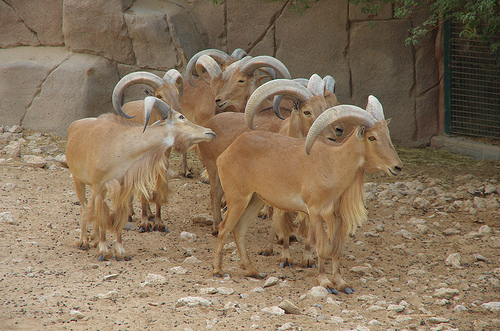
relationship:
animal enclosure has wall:
[1, 0, 498, 331] [2, 0, 442, 138]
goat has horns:
[211, 95, 403, 299] [304, 94, 384, 155]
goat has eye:
[66, 98, 217, 263] [179, 113, 185, 121]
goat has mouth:
[215, 55, 291, 108] [216, 101, 227, 108]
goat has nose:
[211, 95, 403, 299] [395, 162, 404, 172]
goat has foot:
[211, 95, 403, 299] [335, 279, 355, 294]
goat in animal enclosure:
[211, 95, 403, 299] [1, 0, 498, 331]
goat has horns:
[66, 98, 217, 263] [141, 95, 173, 136]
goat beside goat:
[211, 95, 403, 299] [66, 98, 217, 263]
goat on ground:
[211, 95, 403, 299] [2, 139, 500, 330]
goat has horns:
[215, 55, 291, 108] [236, 56, 291, 79]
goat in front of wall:
[211, 95, 403, 299] [2, 0, 442, 138]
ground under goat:
[2, 139, 500, 330] [211, 95, 403, 299]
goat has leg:
[211, 95, 403, 299] [211, 189, 253, 278]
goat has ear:
[211, 95, 403, 299] [357, 125, 366, 141]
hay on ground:
[399, 145, 478, 169] [2, 139, 500, 330]